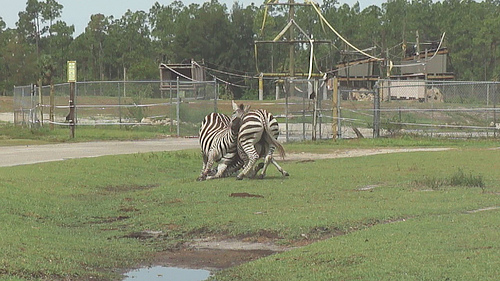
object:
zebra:
[195, 99, 251, 181]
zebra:
[232, 109, 290, 179]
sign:
[64, 59, 78, 83]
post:
[68, 82, 77, 138]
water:
[121, 265, 214, 281]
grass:
[0, 130, 498, 280]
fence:
[11, 79, 499, 146]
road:
[0, 133, 331, 168]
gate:
[175, 75, 220, 138]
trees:
[13, 0, 75, 86]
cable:
[306, 0, 380, 62]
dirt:
[232, 189, 267, 204]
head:
[227, 99, 252, 136]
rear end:
[240, 108, 281, 142]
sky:
[0, 0, 499, 51]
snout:
[229, 117, 243, 132]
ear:
[229, 99, 243, 112]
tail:
[260, 116, 286, 160]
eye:
[231, 110, 239, 116]